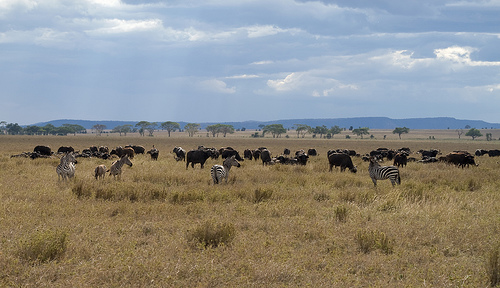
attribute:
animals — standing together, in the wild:
[171, 128, 422, 191]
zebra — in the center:
[209, 153, 245, 189]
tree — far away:
[153, 116, 184, 140]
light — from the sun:
[151, 49, 362, 112]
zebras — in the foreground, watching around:
[50, 145, 142, 186]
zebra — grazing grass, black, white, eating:
[88, 162, 116, 187]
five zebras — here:
[42, 146, 409, 199]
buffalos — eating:
[86, 141, 151, 160]